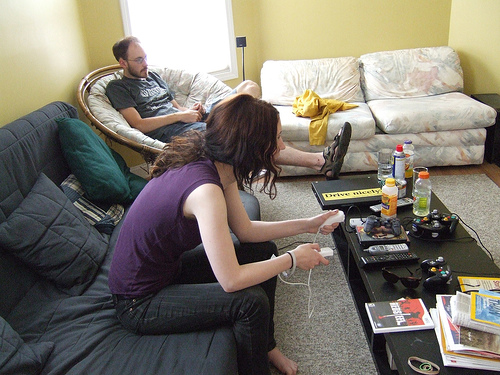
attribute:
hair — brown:
[139, 90, 279, 183]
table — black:
[305, 167, 494, 373]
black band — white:
[286, 248, 293, 268]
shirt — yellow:
[294, 90, 359, 145]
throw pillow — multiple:
[6, 177, 110, 294]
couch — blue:
[3, 97, 261, 372]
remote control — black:
[362, 240, 447, 276]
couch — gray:
[0, 113, 207, 360]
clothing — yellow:
[288, 87, 355, 142]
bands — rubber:
[392, 331, 443, 373]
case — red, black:
[360, 295, 441, 341]